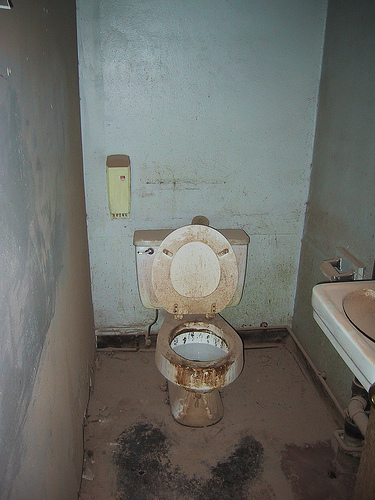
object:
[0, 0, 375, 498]
bathroom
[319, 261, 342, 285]
paper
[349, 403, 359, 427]
pipe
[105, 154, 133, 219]
air freshener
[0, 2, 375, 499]
wall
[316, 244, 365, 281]
holder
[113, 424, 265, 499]
spot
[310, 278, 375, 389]
sink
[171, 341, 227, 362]
water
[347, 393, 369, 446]
pipes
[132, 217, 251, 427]
bathroom toilet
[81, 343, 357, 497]
bathroom floor